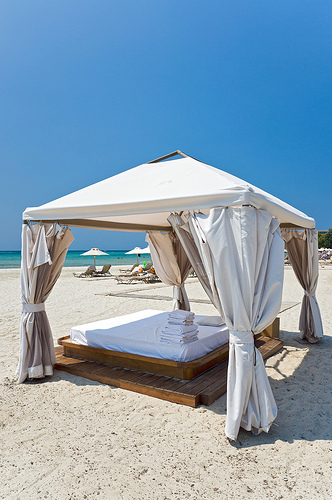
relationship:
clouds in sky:
[2, 1, 308, 260] [1, 1, 321, 265]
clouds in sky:
[0, 0, 332, 253] [1, 1, 321, 265]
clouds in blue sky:
[0, 0, 332, 253] [60, 67, 214, 129]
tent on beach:
[19, 149, 323, 439] [0, 262, 328, 498]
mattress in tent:
[70, 310, 228, 365] [6, 143, 321, 454]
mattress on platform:
[70, 310, 226, 365] [48, 334, 225, 407]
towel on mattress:
[178, 306, 196, 319] [94, 315, 171, 371]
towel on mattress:
[169, 319, 186, 330] [94, 315, 171, 371]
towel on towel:
[171, 322, 193, 335] [178, 306, 196, 319]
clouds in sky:
[0, 0, 332, 253] [172, 27, 236, 86]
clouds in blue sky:
[0, 0, 332, 253] [1, 1, 331, 250]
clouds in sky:
[0, 0, 332, 253] [4, 46, 285, 147]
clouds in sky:
[0, 0, 332, 253] [74, 36, 276, 117]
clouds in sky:
[0, 0, 332, 253] [3, 4, 331, 153]